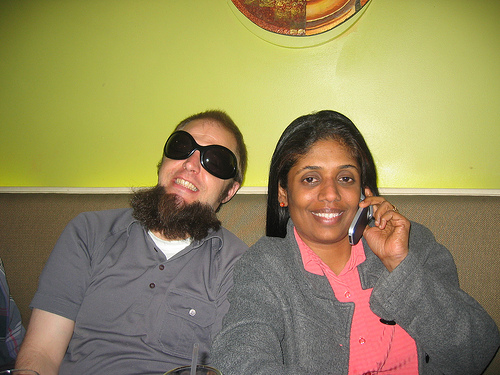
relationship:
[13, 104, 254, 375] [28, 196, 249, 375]
man wearing shirt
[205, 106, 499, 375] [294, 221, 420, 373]
woman wearing shirt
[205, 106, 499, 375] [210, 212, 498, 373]
woman wearing shirt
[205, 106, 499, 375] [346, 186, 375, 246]
woman talking on cell phone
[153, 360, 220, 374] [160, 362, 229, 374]
cup has rim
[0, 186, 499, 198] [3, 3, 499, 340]
strip on wall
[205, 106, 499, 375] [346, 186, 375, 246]
woman using cell phone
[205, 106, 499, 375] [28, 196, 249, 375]
woman wearing shirt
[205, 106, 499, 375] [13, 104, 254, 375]
woman next to man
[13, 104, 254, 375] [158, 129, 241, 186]
man wearing sunglasses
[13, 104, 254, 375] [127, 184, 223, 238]
man has beard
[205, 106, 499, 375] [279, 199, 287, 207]
woman wearing earring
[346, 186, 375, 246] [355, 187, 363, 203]
cell phone on ear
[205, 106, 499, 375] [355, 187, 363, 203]
woman has ear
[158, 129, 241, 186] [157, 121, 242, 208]
sunglasses are on face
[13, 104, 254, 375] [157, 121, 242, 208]
man has face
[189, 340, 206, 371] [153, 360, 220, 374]
straw in cup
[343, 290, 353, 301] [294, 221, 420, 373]
button on shirt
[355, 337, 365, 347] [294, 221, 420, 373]
button on shirt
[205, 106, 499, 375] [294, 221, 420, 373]
woman has shirt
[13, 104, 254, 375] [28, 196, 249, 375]
man has shirt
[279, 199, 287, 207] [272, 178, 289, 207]
earring in ear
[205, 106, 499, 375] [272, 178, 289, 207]
woman has ear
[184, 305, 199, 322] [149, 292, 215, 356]
button on pocket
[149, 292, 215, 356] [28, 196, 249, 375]
pocket on shirt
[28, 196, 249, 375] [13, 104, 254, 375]
shirt on man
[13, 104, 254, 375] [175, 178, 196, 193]
man has teeth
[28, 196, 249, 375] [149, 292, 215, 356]
shirt has pocket